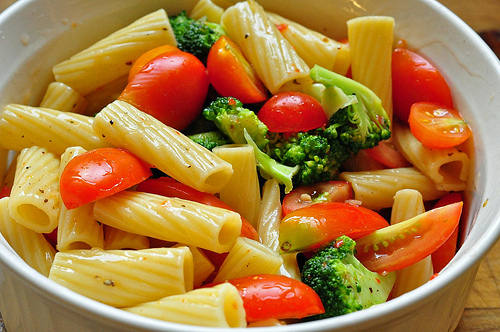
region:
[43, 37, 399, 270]
tomatoes on the pasta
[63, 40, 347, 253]
tomatoes on the pasta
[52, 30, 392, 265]
tomatoes on the pasta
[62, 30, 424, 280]
tomatoes on the pasta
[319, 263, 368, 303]
brocoli in the bowl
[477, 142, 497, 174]
the bowl is white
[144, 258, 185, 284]
pasta noodles in the bowl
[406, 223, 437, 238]
a red tomatoe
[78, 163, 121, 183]
a tomoatoe that is red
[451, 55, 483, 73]
sauce on the bowl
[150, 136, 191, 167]
the noodle is yellow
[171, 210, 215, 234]
a yellow noodle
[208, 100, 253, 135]
the green brocolli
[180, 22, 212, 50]
brocoli in the bowl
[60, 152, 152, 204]
The tomato slice on the left.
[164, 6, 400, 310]
The broccoli in the bowl.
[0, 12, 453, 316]
The noodles in the bowl.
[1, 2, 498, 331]
The white bowl the food is in.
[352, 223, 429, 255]
The seeds on the slice of tomato on the right.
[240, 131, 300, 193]
The stem of the broccoli in the middle of the bowl.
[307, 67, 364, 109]
The stem of the broccoli on the right.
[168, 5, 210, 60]
The top of the broccoli at the top of the bowl.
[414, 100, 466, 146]
The small half piece of tomato on the right.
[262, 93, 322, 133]
a small tomato half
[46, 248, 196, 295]
a white rigatoni noodle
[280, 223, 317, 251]
the green tip of a tomato half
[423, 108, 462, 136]
seeds in a tomato half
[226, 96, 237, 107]
a red pepper flake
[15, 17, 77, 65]
dressing splatters on the side of a bowl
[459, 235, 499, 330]
brown laminate counter top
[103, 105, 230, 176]
ridges along the top of a piece of rigatoni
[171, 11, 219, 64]
the dark green top of a broccoli floret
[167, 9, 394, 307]
the green broccoli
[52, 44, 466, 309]
the sliced tomatoes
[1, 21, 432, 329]
the off white noodles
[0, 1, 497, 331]
a white bowl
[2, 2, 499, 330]
a wooden table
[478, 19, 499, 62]
a dark spot on table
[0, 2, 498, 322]
a salad in bowl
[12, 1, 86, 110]
crumbs on side of bowl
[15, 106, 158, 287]
seasoning on noodles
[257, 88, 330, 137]
Red tomato with moisture on it